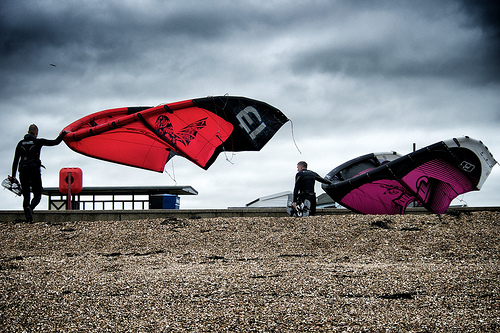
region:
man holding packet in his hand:
[0, 171, 35, 209]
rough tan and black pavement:
[37, 224, 488, 330]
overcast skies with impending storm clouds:
[210, 6, 499, 68]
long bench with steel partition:
[38, 181, 218, 217]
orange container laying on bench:
[53, 166, 85, 201]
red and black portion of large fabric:
[59, 94, 156, 164]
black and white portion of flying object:
[225, 79, 293, 170]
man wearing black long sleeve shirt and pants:
[7, 119, 44, 215]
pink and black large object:
[334, 134, 481, 220]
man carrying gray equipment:
[282, 191, 321, 223]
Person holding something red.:
[6, 93, 286, 210]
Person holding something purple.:
[275, 125, 495, 220]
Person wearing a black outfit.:
[10, 110, 65, 230]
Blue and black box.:
[142, 187, 179, 214]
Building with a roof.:
[30, 182, 196, 212]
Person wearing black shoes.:
[0, 125, 75, 230]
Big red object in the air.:
[60, 85, 287, 170]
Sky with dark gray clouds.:
[7, 12, 482, 203]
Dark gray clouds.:
[287, 6, 488, 91]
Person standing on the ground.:
[6, 114, 69, 230]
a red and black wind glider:
[60, 97, 293, 177]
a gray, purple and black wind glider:
[322, 134, 497, 217]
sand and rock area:
[0, 215, 499, 331]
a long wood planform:
[0, 205, 499, 215]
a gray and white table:
[27, 185, 201, 196]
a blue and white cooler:
[147, 191, 180, 211]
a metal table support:
[44, 193, 151, 209]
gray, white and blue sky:
[0, 0, 498, 210]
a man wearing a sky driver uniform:
[2, 124, 70, 225]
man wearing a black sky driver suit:
[287, 159, 336, 214]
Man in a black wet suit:
[5, 121, 65, 219]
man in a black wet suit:
[286, 158, 332, 215]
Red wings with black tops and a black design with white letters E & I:
[58, 91, 293, 178]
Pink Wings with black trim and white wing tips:
[323, 133, 497, 216]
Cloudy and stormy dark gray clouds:
[1, 3, 494, 94]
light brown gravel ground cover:
[8, 228, 492, 326]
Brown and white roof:
[42, 179, 210, 208]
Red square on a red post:
[53, 160, 85, 214]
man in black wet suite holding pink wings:
[289, 141, 499, 203]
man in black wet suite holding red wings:
[7, 93, 283, 206]